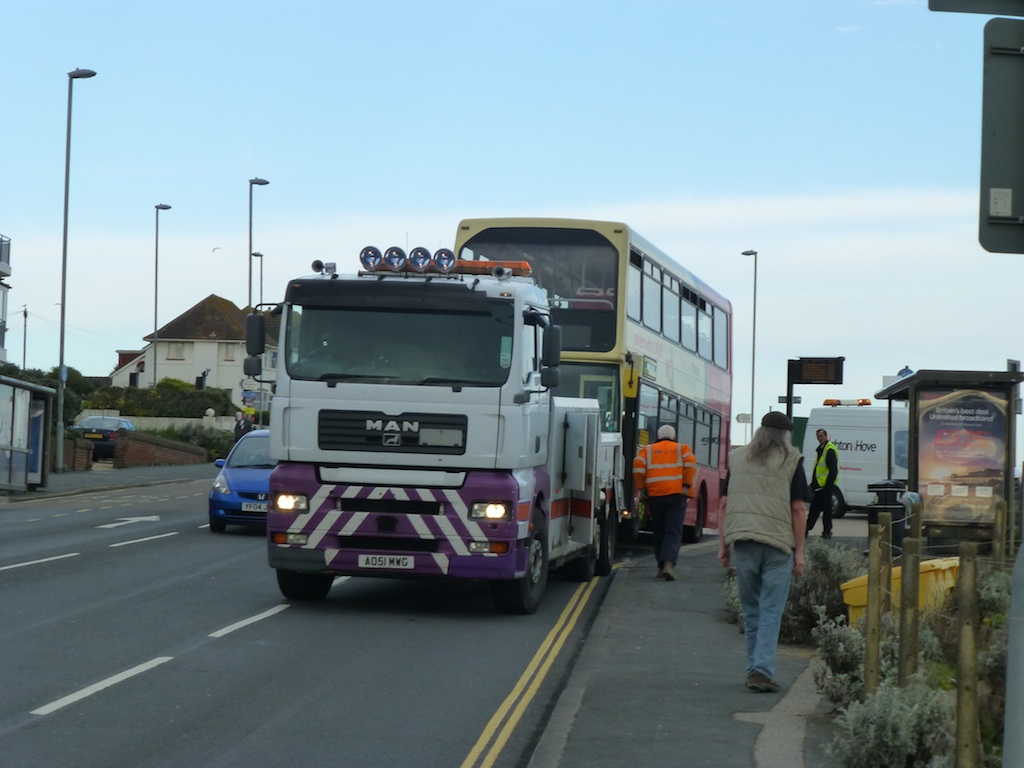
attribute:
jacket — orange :
[634, 441, 696, 498]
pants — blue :
[648, 493, 687, 571]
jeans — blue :
[732, 545, 794, 686]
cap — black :
[760, 411, 795, 434]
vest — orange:
[644, 438, 684, 497]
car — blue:
[210, 427, 277, 535]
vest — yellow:
[811, 441, 840, 487]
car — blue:
[205, 424, 276, 532]